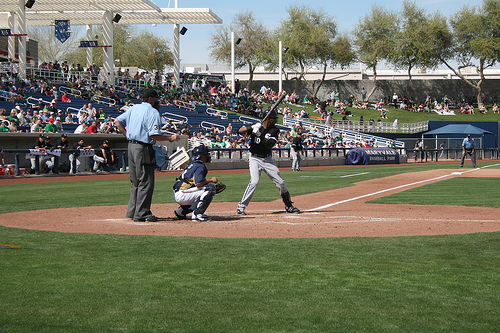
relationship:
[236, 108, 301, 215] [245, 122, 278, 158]
baseball player wearing shirt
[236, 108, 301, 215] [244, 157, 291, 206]
baseball player wearing pants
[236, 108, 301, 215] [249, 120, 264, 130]
baseball player wearing glove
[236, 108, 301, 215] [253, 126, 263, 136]
baseball player wearing glove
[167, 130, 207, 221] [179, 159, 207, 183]
catcher wearing top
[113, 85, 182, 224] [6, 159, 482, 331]
person standing on field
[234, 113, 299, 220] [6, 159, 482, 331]
person standing on field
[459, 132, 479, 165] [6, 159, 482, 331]
person standing on field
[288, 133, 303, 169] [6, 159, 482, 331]
person standing on field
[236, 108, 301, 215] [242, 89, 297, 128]
baseball player holding bat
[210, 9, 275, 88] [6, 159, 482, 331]
tree outside field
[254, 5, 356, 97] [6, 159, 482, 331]
tree outside field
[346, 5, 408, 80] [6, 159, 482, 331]
tree outside field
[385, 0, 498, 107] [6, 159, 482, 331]
tree outside field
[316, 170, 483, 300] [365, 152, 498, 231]
lines on field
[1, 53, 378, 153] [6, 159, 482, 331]
men on field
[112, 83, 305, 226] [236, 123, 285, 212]
men in uniform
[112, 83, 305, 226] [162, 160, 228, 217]
men in uniform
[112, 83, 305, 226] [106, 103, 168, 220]
men in uniform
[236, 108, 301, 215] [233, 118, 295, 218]
baseball player in uniform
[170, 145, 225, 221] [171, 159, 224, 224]
uniformed men in uniform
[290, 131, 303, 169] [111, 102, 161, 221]
uniformed men in uniform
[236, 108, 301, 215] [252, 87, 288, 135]
baseball player swinging bat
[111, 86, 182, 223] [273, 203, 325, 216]
umpire at home plate